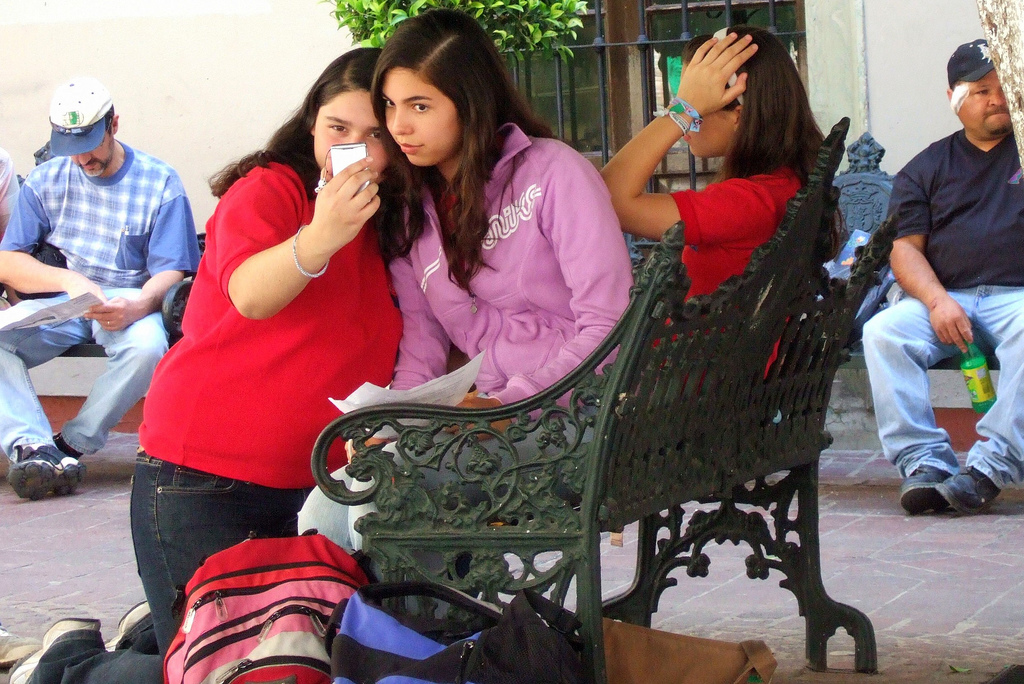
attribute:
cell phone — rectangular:
[319, 130, 386, 195]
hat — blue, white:
[40, 61, 123, 163]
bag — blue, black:
[315, 573, 603, 679]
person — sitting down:
[862, 39, 1022, 517]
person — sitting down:
[602, 26, 810, 452]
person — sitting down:
[0, 80, 193, 495]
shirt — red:
[138, 162, 400, 489]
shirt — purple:
[386, 121, 631, 422]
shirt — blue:
[888, 131, 1016, 287]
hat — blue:
[948, 37, 994, 85]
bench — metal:
[270, 115, 899, 680]